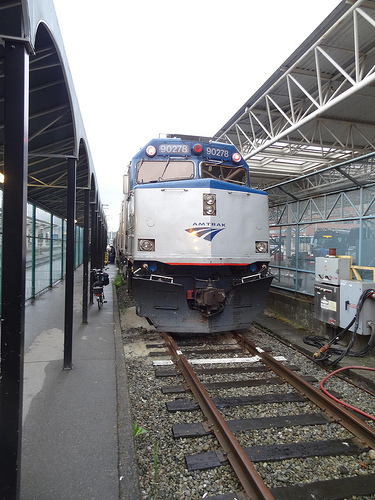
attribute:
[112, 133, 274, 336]
train — blue, silver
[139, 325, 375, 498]
tracks — brown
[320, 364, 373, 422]
hose — orange, red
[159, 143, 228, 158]
number — white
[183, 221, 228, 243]
logo — amtrak, blue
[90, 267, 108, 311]
bicycle — parked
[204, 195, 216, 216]
headlight — round, white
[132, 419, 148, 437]
plant — green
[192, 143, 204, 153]
light — red, round